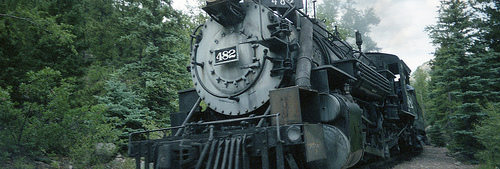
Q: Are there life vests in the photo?
A: No, there are no life vests.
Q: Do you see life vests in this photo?
A: No, there are no life vests.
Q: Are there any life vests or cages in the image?
A: No, there are no life vests or cages.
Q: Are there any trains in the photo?
A: Yes, there is a train.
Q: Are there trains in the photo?
A: Yes, there is a train.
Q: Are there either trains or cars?
A: Yes, there is a train.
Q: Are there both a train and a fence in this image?
A: No, there is a train but no fences.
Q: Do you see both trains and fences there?
A: No, there is a train but no fences.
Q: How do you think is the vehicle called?
A: The vehicle is a train.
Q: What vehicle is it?
A: The vehicle is a train.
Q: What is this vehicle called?
A: That is a train.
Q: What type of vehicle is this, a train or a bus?
A: That is a train.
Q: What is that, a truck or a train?
A: That is a train.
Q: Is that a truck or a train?
A: That is a train.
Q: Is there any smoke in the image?
A: Yes, there is smoke.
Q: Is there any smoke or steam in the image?
A: Yes, there is smoke.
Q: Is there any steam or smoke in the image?
A: Yes, there is smoke.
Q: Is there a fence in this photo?
A: No, there are no fences.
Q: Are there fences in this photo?
A: No, there are no fences.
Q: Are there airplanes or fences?
A: No, there are no fences or airplanes.